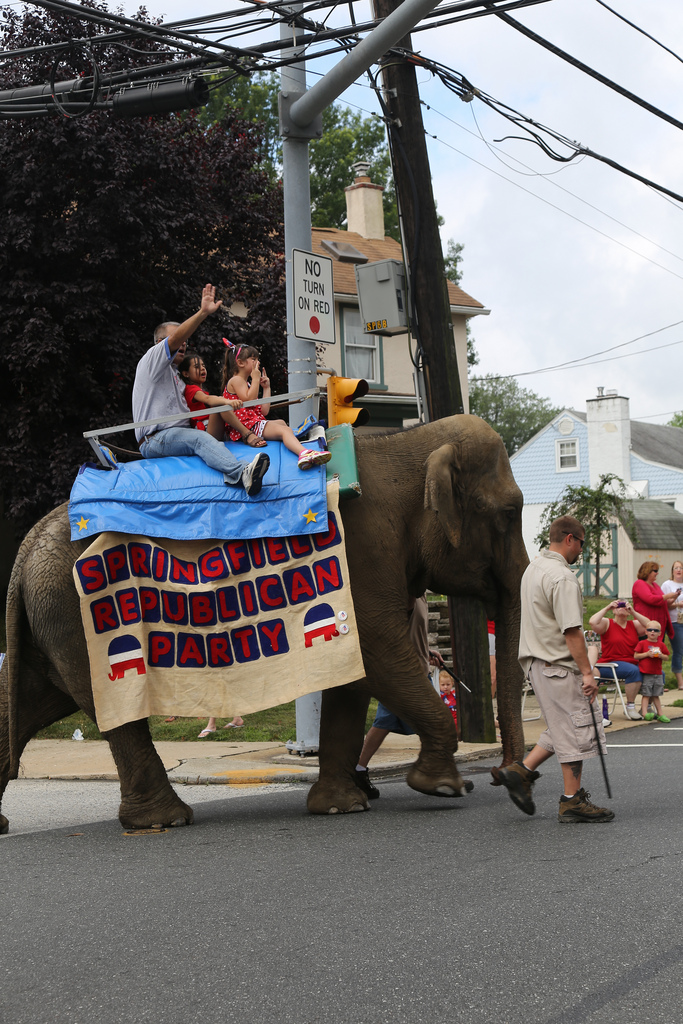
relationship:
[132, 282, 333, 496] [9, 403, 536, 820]
man/two kids riding elephant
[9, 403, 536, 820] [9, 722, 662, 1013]
elephant on street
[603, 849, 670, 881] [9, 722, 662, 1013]
crack on street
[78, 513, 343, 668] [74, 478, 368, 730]
writing on item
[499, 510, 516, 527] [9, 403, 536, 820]
eye of elephant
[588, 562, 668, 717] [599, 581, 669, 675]
people wearing clothing